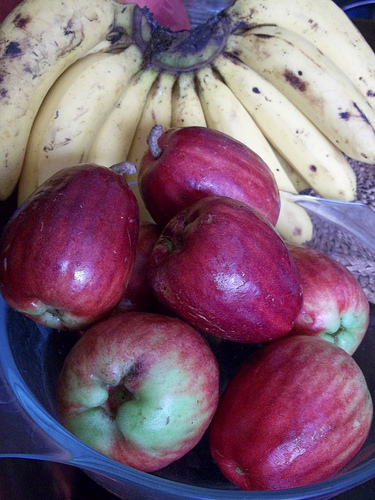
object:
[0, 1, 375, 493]
fruit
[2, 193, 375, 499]
bowl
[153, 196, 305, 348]
piece of fruit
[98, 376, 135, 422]
hole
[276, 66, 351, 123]
brown parts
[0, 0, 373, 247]
bananas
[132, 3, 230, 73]
stem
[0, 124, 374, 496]
apples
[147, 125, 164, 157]
stem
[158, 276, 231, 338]
marks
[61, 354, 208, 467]
marks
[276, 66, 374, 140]
marks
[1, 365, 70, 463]
handle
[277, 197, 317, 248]
tip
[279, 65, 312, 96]
dark spots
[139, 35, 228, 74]
dark spaces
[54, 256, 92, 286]
light